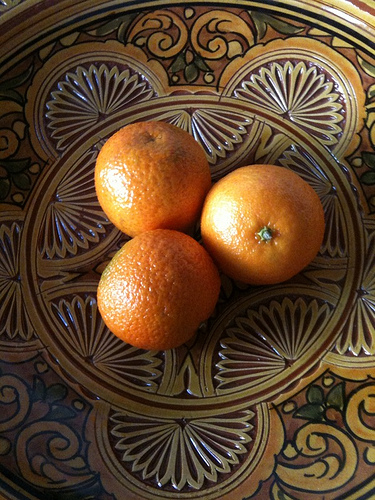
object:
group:
[93, 121, 326, 351]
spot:
[140, 130, 160, 146]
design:
[0, 0, 375, 500]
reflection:
[212, 196, 238, 245]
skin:
[200, 163, 325, 284]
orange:
[93, 121, 325, 351]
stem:
[257, 226, 275, 242]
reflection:
[100, 161, 138, 208]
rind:
[97, 230, 221, 350]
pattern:
[15, 420, 96, 489]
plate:
[0, 0, 372, 498]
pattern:
[172, 46, 214, 83]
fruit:
[94, 121, 211, 238]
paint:
[125, 3, 258, 86]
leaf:
[292, 381, 346, 423]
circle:
[18, 93, 365, 420]